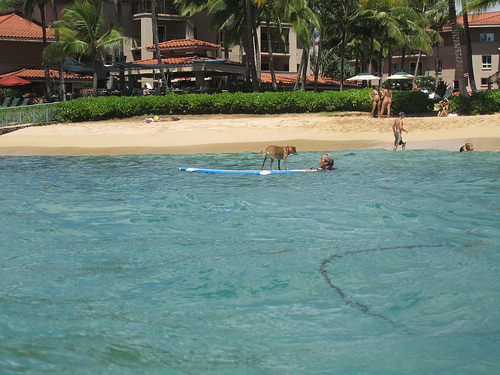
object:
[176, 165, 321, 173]
surfboard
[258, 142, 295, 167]
dog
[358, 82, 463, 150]
tourist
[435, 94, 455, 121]
woman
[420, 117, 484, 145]
sand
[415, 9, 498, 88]
house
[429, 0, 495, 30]
roof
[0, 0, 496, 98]
timeshare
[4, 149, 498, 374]
ocean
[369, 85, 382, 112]
woman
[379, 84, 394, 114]
woman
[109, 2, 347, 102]
palm trees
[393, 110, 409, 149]
person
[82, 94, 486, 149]
beach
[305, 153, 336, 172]
vacationer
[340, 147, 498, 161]
seashore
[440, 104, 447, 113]
wetsuit